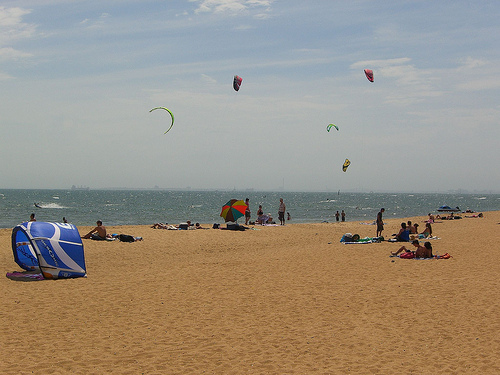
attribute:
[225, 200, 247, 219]
umbrella — multicolored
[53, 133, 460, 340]
beach — sandy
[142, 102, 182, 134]
most sail — green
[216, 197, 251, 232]
umbrella — multicolored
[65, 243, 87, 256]
blue — white, large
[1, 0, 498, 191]
sky — cloudy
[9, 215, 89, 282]
tent — blue, white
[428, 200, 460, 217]
boat — small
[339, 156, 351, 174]
sail — black, yellow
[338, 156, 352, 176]
kite — black, yellow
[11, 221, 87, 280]
arch — blue